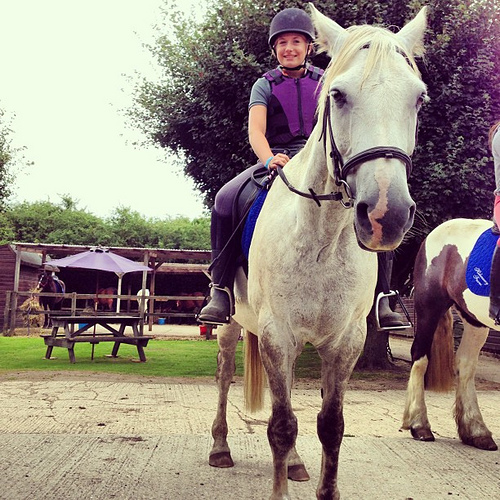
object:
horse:
[403, 198, 499, 438]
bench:
[38, 311, 149, 363]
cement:
[39, 381, 188, 456]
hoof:
[205, 448, 235, 471]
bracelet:
[264, 155, 272, 170]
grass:
[162, 343, 196, 370]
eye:
[328, 87, 348, 110]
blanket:
[239, 189, 262, 256]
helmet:
[267, 7, 315, 45]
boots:
[195, 281, 229, 324]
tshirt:
[251, 64, 329, 160]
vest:
[269, 66, 321, 152]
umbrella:
[38, 237, 152, 317]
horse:
[34, 266, 65, 327]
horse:
[135, 285, 152, 322]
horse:
[95, 285, 115, 310]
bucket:
[199, 323, 213, 336]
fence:
[105, 261, 242, 348]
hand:
[264, 149, 289, 169]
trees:
[47, 210, 207, 271]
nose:
[284, 38, 293, 53]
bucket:
[157, 315, 166, 326]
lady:
[192, 8, 324, 326]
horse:
[196, 0, 425, 500]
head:
[272, 27, 312, 69]